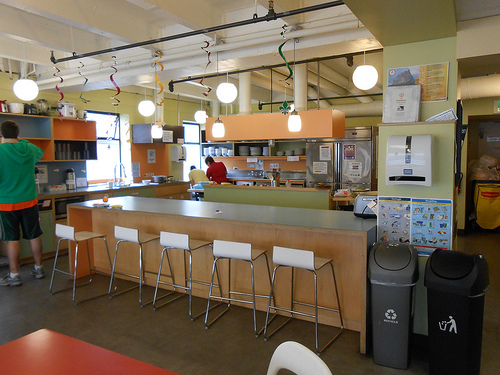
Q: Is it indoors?
A: Yes, it is indoors.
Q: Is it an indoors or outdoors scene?
A: It is indoors.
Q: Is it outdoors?
A: No, it is indoors.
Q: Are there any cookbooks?
A: No, there are no cookbooks.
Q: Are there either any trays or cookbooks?
A: No, there are no cookbooks or trays.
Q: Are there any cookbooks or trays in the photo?
A: No, there are no cookbooks or trays.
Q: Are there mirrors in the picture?
A: No, there are no mirrors.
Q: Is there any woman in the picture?
A: Yes, there is a woman.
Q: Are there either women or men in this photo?
A: Yes, there is a woman.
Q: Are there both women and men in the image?
A: Yes, there are both a woman and a man.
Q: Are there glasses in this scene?
A: No, there are no glasses.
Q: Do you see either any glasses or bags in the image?
A: No, there are no glasses or bags.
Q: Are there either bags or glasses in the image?
A: No, there are no glasses or bags.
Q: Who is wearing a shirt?
A: The woman is wearing a shirt.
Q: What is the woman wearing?
A: The woman is wearing a shirt.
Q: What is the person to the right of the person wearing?
A: The woman is wearing a shirt.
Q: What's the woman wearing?
A: The woman is wearing a shirt.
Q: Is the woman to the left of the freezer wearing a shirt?
A: Yes, the woman is wearing a shirt.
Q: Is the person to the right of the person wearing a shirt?
A: Yes, the woman is wearing a shirt.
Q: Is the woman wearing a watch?
A: No, the woman is wearing a shirt.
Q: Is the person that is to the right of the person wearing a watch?
A: No, the woman is wearing a shirt.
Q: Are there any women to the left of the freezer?
A: Yes, there is a woman to the left of the freezer.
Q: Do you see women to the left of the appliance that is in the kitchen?
A: Yes, there is a woman to the left of the freezer.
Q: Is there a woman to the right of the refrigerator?
A: No, the woman is to the left of the refrigerator.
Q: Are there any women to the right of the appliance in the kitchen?
A: No, the woman is to the left of the refrigerator.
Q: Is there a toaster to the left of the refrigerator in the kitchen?
A: No, there is a woman to the left of the fridge.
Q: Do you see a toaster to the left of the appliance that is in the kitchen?
A: No, there is a woman to the left of the fridge.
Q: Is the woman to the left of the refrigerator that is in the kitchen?
A: Yes, the woman is to the left of the freezer.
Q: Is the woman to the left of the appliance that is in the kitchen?
A: Yes, the woman is to the left of the freezer.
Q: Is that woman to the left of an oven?
A: No, the woman is to the left of the freezer.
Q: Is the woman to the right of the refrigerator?
A: No, the woman is to the left of the refrigerator.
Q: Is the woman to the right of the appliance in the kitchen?
A: No, the woman is to the left of the refrigerator.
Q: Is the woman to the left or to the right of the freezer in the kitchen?
A: The woman is to the left of the fridge.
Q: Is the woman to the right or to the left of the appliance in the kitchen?
A: The woman is to the left of the fridge.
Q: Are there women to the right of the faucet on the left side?
A: Yes, there is a woman to the right of the faucet.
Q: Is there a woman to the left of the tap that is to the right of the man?
A: No, the woman is to the right of the faucet.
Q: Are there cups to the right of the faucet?
A: No, there is a woman to the right of the faucet.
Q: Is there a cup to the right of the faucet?
A: No, there is a woman to the right of the faucet.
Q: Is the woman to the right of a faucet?
A: Yes, the woman is to the right of a faucet.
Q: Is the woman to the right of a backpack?
A: No, the woman is to the right of a faucet.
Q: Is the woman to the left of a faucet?
A: No, the woman is to the right of a faucet.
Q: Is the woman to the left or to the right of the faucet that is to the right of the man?
A: The woman is to the right of the faucet.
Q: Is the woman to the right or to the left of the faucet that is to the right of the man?
A: The woman is to the right of the faucet.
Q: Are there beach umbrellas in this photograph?
A: No, there are no beach umbrellas.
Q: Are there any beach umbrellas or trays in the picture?
A: No, there are no beach umbrellas or trays.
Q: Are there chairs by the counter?
A: Yes, there are chairs by the counter.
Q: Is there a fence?
A: No, there are no fences.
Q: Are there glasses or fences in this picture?
A: No, there are no fences or glasses.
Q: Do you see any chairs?
A: Yes, there is a chair.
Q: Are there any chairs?
A: Yes, there is a chair.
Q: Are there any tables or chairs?
A: Yes, there is a chair.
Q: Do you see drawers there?
A: No, there are no drawers.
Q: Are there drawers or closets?
A: No, there are no drawers or closets.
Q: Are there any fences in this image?
A: No, there are no fences.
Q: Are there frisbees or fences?
A: No, there are no fences or frisbees.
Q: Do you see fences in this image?
A: No, there are no fences.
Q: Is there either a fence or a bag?
A: No, there are no fences or bags.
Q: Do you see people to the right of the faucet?
A: Yes, there is a person to the right of the faucet.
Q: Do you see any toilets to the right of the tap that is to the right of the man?
A: No, there is a person to the right of the tap.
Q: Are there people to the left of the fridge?
A: Yes, there is a person to the left of the fridge.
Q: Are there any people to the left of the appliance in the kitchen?
A: Yes, there is a person to the left of the fridge.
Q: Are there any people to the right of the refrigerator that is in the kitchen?
A: No, the person is to the left of the refrigerator.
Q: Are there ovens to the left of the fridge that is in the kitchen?
A: No, there is a person to the left of the fridge.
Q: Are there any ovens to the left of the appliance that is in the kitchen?
A: No, there is a person to the left of the fridge.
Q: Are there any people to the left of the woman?
A: Yes, there is a person to the left of the woman.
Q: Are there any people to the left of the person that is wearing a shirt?
A: Yes, there is a person to the left of the woman.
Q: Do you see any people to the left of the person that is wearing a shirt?
A: Yes, there is a person to the left of the woman.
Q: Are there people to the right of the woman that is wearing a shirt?
A: No, the person is to the left of the woman.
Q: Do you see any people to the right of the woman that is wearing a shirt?
A: No, the person is to the left of the woman.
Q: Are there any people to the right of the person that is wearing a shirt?
A: No, the person is to the left of the woman.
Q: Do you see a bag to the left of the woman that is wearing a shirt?
A: No, there is a person to the left of the woman.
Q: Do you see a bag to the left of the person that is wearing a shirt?
A: No, there is a person to the left of the woman.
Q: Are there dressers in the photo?
A: No, there are no dressers.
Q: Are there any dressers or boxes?
A: No, there are no dressers or boxes.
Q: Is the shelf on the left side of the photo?
A: Yes, the shelf is on the left of the image.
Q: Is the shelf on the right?
A: No, the shelf is on the left of the image.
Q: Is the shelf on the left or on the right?
A: The shelf is on the left of the image.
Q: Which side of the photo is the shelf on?
A: The shelf is on the left of the image.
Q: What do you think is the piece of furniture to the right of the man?
A: The piece of furniture is a shelf.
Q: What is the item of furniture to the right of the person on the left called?
A: The piece of furniture is a shelf.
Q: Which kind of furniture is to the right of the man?
A: The piece of furniture is a shelf.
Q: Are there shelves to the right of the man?
A: Yes, there is a shelf to the right of the man.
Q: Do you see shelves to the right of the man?
A: Yes, there is a shelf to the right of the man.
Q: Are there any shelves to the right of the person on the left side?
A: Yes, there is a shelf to the right of the man.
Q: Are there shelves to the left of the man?
A: No, the shelf is to the right of the man.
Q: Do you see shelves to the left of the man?
A: No, the shelf is to the right of the man.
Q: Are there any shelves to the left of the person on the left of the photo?
A: No, the shelf is to the right of the man.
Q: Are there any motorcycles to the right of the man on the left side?
A: No, there is a shelf to the right of the man.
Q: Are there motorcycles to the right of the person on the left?
A: No, there is a shelf to the right of the man.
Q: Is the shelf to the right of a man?
A: Yes, the shelf is to the right of a man.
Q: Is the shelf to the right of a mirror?
A: No, the shelf is to the right of a man.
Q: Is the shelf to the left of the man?
A: No, the shelf is to the right of the man.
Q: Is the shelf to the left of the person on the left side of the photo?
A: No, the shelf is to the right of the man.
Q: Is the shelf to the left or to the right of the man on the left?
A: The shelf is to the right of the man.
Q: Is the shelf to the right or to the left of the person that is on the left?
A: The shelf is to the right of the man.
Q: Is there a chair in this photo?
A: Yes, there is a chair.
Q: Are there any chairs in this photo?
A: Yes, there is a chair.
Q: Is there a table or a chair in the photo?
A: Yes, there is a chair.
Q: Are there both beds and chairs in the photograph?
A: No, there is a chair but no beds.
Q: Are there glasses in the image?
A: No, there are no glasses.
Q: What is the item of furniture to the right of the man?
A: The piece of furniture is a chair.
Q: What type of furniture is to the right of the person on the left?
A: The piece of furniture is a chair.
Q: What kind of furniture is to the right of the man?
A: The piece of furniture is a chair.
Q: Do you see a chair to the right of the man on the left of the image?
A: Yes, there is a chair to the right of the man.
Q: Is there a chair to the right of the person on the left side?
A: Yes, there is a chair to the right of the man.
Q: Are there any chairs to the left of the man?
A: No, the chair is to the right of the man.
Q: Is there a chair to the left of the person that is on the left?
A: No, the chair is to the right of the man.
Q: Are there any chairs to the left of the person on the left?
A: No, the chair is to the right of the man.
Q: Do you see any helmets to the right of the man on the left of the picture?
A: No, there is a chair to the right of the man.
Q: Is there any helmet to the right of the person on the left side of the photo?
A: No, there is a chair to the right of the man.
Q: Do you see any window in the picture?
A: Yes, there is a window.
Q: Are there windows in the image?
A: Yes, there is a window.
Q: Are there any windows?
A: Yes, there is a window.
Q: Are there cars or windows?
A: Yes, there is a window.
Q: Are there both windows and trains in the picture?
A: No, there is a window but no trains.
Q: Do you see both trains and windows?
A: No, there is a window but no trains.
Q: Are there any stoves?
A: No, there are no stoves.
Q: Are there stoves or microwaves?
A: No, there are no stoves or microwaves.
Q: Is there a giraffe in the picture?
A: No, there are no giraffes.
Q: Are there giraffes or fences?
A: No, there are no giraffes or fences.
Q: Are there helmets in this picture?
A: No, there are no helmets.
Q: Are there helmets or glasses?
A: No, there are no helmets or glasses.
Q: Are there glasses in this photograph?
A: No, there are no glasses.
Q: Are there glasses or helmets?
A: No, there are no glasses or helmets.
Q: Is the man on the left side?
A: Yes, the man is on the left of the image.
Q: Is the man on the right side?
A: No, the man is on the left of the image.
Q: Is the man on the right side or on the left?
A: The man is on the left of the image.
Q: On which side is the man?
A: The man is on the left of the image.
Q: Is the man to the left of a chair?
A: Yes, the man is to the left of a chair.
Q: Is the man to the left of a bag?
A: No, the man is to the left of a chair.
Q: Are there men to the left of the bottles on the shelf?
A: Yes, there is a man to the left of the bottles.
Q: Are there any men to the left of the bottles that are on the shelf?
A: Yes, there is a man to the left of the bottles.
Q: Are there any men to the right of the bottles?
A: No, the man is to the left of the bottles.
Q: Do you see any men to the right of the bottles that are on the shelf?
A: No, the man is to the left of the bottles.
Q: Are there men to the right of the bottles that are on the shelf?
A: No, the man is to the left of the bottles.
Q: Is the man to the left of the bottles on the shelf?
A: Yes, the man is to the left of the bottles.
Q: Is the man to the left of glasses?
A: No, the man is to the left of the bottles.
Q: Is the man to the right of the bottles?
A: No, the man is to the left of the bottles.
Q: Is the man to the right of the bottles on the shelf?
A: No, the man is to the left of the bottles.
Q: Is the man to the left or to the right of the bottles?
A: The man is to the left of the bottles.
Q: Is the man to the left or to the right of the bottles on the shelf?
A: The man is to the left of the bottles.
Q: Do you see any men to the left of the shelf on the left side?
A: Yes, there is a man to the left of the shelf.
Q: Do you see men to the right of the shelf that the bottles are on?
A: No, the man is to the left of the shelf.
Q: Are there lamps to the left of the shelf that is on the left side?
A: No, there is a man to the left of the shelf.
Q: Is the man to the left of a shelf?
A: Yes, the man is to the left of a shelf.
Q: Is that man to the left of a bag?
A: No, the man is to the left of a shelf.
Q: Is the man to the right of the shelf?
A: No, the man is to the left of the shelf.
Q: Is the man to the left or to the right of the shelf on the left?
A: The man is to the left of the shelf.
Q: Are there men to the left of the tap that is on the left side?
A: Yes, there is a man to the left of the faucet.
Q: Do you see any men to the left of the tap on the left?
A: Yes, there is a man to the left of the faucet.